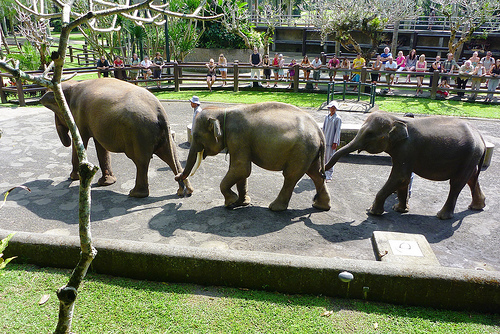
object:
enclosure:
[3, 67, 483, 304]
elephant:
[35, 76, 190, 199]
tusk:
[174, 142, 206, 182]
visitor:
[234, 34, 446, 82]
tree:
[41, 81, 104, 334]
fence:
[225, 53, 415, 97]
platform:
[201, 216, 384, 248]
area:
[131, 290, 315, 328]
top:
[250, 53, 262, 67]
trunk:
[151, 130, 207, 200]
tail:
[152, 115, 188, 184]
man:
[319, 100, 343, 178]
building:
[242, 1, 473, 53]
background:
[96, 14, 471, 116]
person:
[203, 57, 219, 93]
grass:
[101, 279, 195, 319]